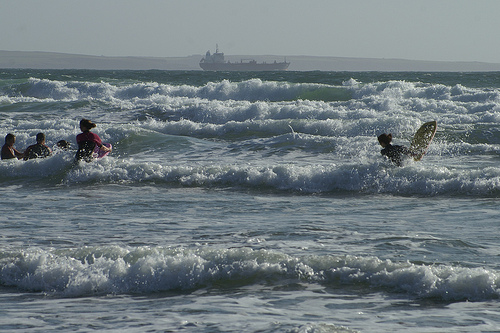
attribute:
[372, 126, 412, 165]
person — surfing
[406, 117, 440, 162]
boogie board — yellow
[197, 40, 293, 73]
ship — large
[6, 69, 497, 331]
water — white, choppy, crashing, angry, small, rough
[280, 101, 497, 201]
wave — thin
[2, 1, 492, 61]
sky — gray, clear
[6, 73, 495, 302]
waves — big